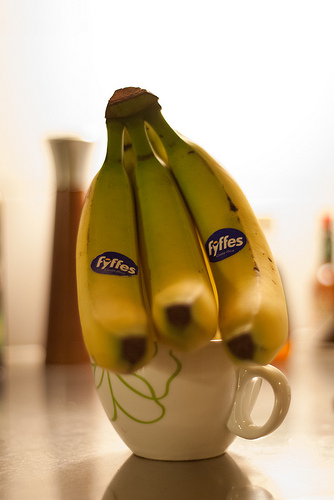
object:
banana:
[127, 118, 220, 347]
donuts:
[232, 30, 238, 222]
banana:
[147, 104, 288, 366]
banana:
[75, 117, 150, 375]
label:
[206, 228, 248, 262]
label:
[90, 251, 138, 276]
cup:
[88, 340, 290, 464]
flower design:
[91, 340, 181, 425]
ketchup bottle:
[42, 135, 94, 365]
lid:
[47, 137, 92, 185]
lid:
[322, 216, 331, 229]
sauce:
[316, 211, 333, 317]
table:
[3, 422, 90, 483]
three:
[75, 86, 290, 376]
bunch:
[75, 86, 287, 374]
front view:
[3, 241, 316, 468]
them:
[76, 222, 283, 373]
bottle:
[313, 263, 334, 350]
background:
[0, 235, 333, 476]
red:
[319, 217, 332, 235]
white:
[48, 134, 91, 182]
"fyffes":
[93, 253, 137, 276]